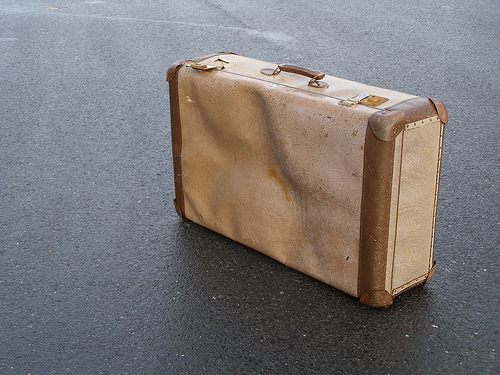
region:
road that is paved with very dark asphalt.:
[16, 234, 194, 349]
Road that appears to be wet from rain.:
[7, 6, 166, 364]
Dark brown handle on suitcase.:
[267, 54, 332, 89]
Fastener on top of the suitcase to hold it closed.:
[336, 86, 386, 114]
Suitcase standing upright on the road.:
[7, 6, 499, 369]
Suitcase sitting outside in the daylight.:
[13, 7, 498, 373]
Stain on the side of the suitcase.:
[260, 165, 302, 208]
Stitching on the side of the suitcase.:
[385, 119, 407, 298]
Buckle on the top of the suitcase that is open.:
[177, 47, 229, 79]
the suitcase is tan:
[282, 169, 360, 255]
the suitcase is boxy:
[245, 199, 336, 257]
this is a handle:
[290, 67, 305, 81]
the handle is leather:
[245, 64, 352, 134]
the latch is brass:
[325, 88, 388, 139]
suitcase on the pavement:
[149, 30, 428, 290]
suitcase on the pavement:
[176, 45, 436, 322]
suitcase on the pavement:
[117, 15, 419, 312]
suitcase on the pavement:
[189, 45, 474, 327]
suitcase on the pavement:
[134, 40, 420, 342]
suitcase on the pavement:
[140, 45, 427, 324]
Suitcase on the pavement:
[139, 35, 477, 332]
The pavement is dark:
[115, 203, 212, 300]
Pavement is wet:
[31, 108, 171, 360]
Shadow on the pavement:
[185, 248, 391, 373]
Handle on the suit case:
[266, 50, 341, 106]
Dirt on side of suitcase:
[236, 103, 331, 220]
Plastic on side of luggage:
[361, 108, 407, 301]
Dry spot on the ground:
[156, 10, 396, 56]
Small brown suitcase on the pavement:
[115, 25, 442, 325]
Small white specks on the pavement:
[17, 331, 39, 359]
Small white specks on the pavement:
[462, 247, 494, 287]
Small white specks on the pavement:
[252, 352, 314, 374]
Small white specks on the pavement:
[288, 315, 322, 352]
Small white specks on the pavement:
[262, 264, 312, 319]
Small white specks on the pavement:
[208, 280, 250, 313]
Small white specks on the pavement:
[197, 239, 262, 284]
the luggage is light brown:
[165, 50, 447, 306]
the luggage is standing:
[166, 50, 449, 304]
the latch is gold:
[338, 91, 368, 108]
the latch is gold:
[188, 58, 226, 69]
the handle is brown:
[260, 62, 329, 89]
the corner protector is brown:
[370, 111, 405, 139]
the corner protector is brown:
[360, 290, 394, 307]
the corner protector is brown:
[425, 261, 437, 283]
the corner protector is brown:
[430, 93, 448, 123]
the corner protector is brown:
[172, 196, 183, 218]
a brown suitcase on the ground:
[174, 35, 461, 280]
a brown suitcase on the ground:
[251, 176, 436, 313]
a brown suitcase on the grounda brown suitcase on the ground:
[177, 151, 383, 281]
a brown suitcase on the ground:
[222, 125, 372, 262]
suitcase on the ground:
[5, 7, 488, 350]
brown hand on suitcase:
[256, 50, 338, 104]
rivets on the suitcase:
[383, 105, 450, 312]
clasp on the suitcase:
[360, 86, 387, 116]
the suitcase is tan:
[159, 39, 474, 312]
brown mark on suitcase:
[260, 162, 296, 211]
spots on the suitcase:
[289, 104, 364, 169]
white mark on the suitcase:
[178, 86, 201, 113]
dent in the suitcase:
[222, 90, 274, 178]